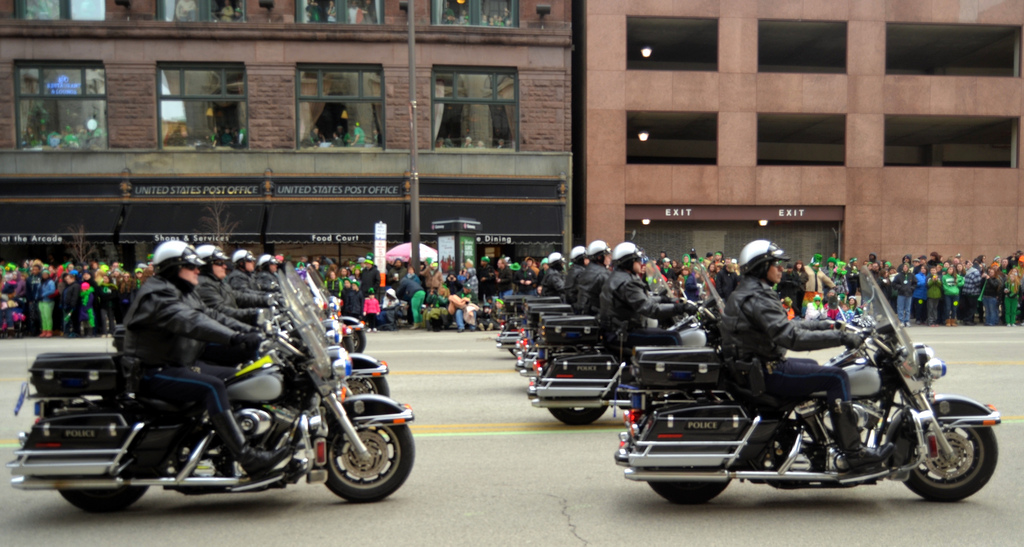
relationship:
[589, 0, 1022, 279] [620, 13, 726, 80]
garage has opening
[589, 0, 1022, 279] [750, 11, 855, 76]
garage has opening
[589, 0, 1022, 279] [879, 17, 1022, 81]
garage has opening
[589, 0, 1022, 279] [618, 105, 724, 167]
garage has opening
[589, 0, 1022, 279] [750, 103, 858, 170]
garage has opening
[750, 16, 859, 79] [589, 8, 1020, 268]
opening in garage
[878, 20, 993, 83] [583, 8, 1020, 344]
opening in garage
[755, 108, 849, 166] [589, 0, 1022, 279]
opening in garage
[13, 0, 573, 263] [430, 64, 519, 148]
building has window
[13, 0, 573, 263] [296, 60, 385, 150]
building has window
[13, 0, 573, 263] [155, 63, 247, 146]
building has window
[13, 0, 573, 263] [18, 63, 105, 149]
building has window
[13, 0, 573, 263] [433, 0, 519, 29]
building has window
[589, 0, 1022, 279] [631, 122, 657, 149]
garage has light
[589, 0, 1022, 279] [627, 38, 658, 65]
garage has light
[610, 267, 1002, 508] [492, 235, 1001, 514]
motorcycle in front row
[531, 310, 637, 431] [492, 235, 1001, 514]
motorcycle in front row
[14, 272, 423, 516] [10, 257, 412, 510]
motorcycle in row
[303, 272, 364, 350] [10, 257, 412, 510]
motorcycle in row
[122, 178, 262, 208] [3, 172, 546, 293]
sign on food court